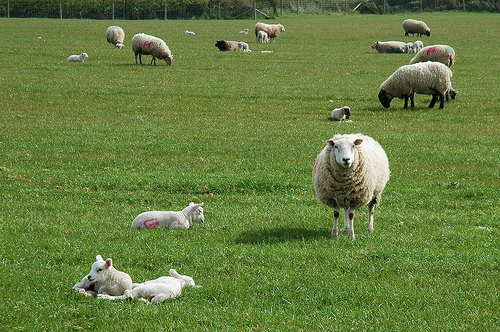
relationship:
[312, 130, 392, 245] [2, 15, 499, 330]
sheep in field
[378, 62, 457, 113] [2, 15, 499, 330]
sheep in field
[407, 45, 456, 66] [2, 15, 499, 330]
sheep in field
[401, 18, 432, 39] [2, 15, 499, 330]
sheep in field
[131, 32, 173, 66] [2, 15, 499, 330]
sheep in field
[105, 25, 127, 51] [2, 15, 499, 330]
sheep in field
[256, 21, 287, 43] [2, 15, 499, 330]
sheep in field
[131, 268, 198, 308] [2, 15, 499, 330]
lamb laying in grass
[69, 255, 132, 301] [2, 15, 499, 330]
lamb laying in grass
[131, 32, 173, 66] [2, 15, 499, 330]
sheep eating grass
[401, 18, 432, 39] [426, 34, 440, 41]
sheep eating grass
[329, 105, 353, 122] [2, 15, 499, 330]
lamb sitting on field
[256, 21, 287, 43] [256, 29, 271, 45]
sheep and lamb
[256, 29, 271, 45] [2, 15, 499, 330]
lamb in field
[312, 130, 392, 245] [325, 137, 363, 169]
sheep has head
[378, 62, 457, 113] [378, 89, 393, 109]
sheep has face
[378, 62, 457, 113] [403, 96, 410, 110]
sheep has leg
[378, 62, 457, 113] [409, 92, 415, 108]
sheep has leg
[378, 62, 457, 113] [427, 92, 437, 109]
sheep has leg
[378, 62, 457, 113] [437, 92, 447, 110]
sheep has leg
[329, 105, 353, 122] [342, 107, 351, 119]
lamb has face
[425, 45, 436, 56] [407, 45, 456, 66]
letter on sheep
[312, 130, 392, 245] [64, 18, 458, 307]
sheep in flock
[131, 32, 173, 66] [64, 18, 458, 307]
sheep in flock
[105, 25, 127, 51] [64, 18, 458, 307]
sheep in flock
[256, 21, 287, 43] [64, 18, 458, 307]
sheep in flock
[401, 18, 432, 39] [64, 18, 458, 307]
sheep in flock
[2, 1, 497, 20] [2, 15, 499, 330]
fence beyond field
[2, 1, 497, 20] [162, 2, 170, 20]
fence has post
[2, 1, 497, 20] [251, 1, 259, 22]
fence has post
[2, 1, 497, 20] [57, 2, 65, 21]
fence has post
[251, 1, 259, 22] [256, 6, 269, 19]
post has brace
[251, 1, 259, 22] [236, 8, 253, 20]
post has brace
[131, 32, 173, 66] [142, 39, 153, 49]
sheep has letter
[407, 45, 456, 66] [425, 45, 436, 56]
sheep has letter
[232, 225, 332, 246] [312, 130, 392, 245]
shadow of sheep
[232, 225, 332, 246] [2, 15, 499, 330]
shadow on field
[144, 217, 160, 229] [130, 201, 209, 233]
marking on lamb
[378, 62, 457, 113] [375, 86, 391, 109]
sheep has head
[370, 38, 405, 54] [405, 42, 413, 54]
sheep has lamb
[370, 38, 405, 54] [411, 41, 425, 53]
sheep has lamb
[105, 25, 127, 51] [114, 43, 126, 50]
sheep has head